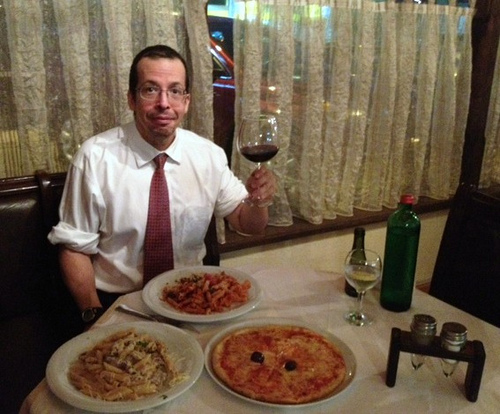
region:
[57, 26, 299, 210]
man next to pizza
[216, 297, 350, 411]
pizza on the plate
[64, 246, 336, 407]
three plates of food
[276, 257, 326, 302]
white table under the plate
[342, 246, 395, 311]
glass on the table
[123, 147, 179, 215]
tie on the man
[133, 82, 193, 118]
glasses on the man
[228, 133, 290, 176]
glass in the man's head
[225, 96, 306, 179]
glass with liquid in it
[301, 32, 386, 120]
curtain behind the man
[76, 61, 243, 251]
this is a man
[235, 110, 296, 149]
this is a glass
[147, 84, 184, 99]
this is a spectacle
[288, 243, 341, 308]
this is a table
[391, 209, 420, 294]
this is a bottle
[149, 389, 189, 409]
this is a plate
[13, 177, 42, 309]
this is a chair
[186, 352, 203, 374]
the plate is white ion color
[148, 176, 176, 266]
this is a neck tie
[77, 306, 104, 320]
this is a watch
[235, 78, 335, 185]
wing glass in man's hand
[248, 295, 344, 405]
pizza on a plate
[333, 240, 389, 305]
wine glass on table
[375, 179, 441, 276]
green bottle with red cap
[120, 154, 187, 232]
red tie on man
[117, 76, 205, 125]
glasses on man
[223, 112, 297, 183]
glass full of liquid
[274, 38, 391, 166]
curtain behind the man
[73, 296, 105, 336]
watch on man's hand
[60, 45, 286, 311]
Man seated at a table.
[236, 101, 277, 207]
Glass of red wine being held by man.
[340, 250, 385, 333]
Glass of white wine on table.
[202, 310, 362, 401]
A pizza on a white plate.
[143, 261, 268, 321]
Paste with red sauce on white plate.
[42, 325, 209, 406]
Pasta with white sauce with white plate.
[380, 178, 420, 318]
Green bottle with red top on table.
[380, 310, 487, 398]
Salt and pepper shakers in brown holder.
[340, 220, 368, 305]
Small green bottle behind wine glass.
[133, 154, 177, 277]
Red tie worn by man at table.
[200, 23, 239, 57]
red shiny car on the outside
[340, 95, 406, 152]
car's light reflecting in the room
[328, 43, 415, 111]
lacy sheer white curtains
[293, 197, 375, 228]
ruffled edge of curtain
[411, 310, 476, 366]
salt and pepper shakers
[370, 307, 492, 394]
black salt and pepper holder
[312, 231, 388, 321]
clear glass of wine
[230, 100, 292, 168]
red wine in glass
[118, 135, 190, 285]
neatly tied red tie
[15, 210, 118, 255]
man's sleeve rolled up